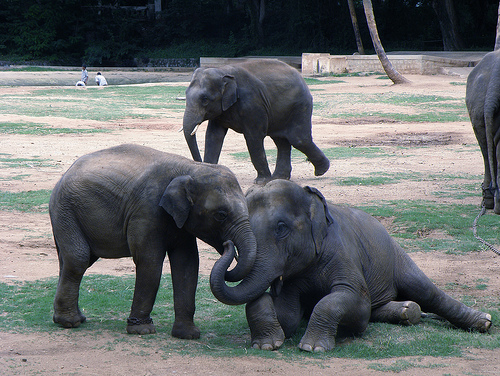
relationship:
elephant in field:
[48, 143, 258, 339] [0, 63, 496, 373]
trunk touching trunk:
[216, 213, 257, 281] [207, 237, 289, 305]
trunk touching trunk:
[207, 237, 289, 305] [216, 213, 257, 281]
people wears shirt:
[94, 71, 108, 85] [94, 75, 106, 85]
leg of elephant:
[297, 264, 373, 355] [210, 179, 489, 352]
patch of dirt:
[317, 115, 474, 150] [2, 315, 492, 375]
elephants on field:
[464, 45, 499, 217] [0, 64, 499, 376]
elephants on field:
[170, 53, 330, 180] [0, 64, 499, 376]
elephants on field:
[207, 177, 494, 355] [0, 64, 499, 376]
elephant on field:
[48, 143, 258, 339] [0, 64, 499, 376]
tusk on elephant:
[184, 120, 201, 151] [177, 48, 335, 184]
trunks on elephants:
[180, 115, 286, 306] [41, 46, 499, 354]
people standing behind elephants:
[71, 63, 112, 89] [40, 131, 481, 345]